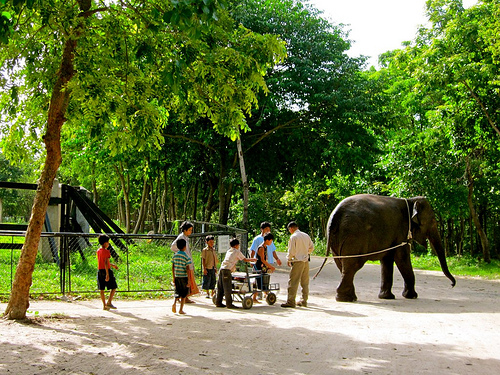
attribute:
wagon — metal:
[230, 267, 280, 317]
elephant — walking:
[308, 191, 455, 300]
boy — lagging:
[91, 231, 122, 312]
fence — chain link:
[0, 220, 249, 295]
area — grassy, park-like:
[2, 221, 246, 294]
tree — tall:
[0, 2, 344, 364]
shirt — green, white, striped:
[176, 255, 186, 275]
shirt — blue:
[253, 235, 276, 259]